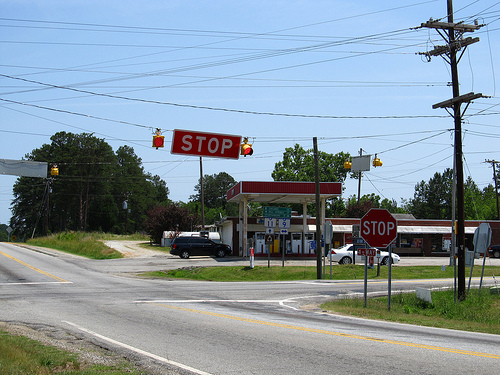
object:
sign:
[169, 128, 243, 161]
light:
[241, 144, 255, 158]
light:
[151, 134, 166, 149]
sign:
[358, 207, 401, 251]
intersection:
[1, 251, 331, 361]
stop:
[362, 218, 392, 236]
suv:
[168, 234, 232, 259]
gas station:
[223, 178, 345, 262]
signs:
[262, 220, 287, 227]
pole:
[279, 234, 287, 269]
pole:
[383, 244, 396, 314]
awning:
[223, 179, 343, 206]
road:
[97, 235, 176, 260]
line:
[1, 249, 67, 280]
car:
[325, 240, 404, 268]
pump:
[250, 230, 267, 257]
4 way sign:
[354, 247, 377, 258]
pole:
[360, 255, 370, 313]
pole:
[309, 135, 323, 282]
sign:
[1, 157, 49, 180]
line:
[168, 299, 498, 362]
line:
[130, 296, 282, 305]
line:
[1, 280, 73, 287]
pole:
[246, 244, 256, 271]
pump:
[288, 230, 304, 257]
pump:
[303, 231, 317, 256]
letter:
[179, 134, 194, 153]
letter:
[193, 133, 208, 153]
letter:
[206, 137, 220, 155]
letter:
[219, 137, 233, 157]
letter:
[361, 218, 371, 237]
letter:
[369, 219, 379, 237]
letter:
[375, 218, 389, 235]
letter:
[384, 220, 395, 238]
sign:
[467, 220, 491, 253]